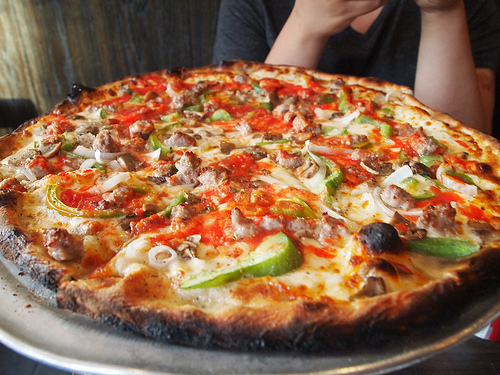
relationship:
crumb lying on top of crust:
[24, 302, 33, 308] [0, 58, 500, 354]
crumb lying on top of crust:
[11, 291, 17, 296] [0, 58, 500, 354]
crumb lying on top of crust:
[16, 270, 26, 277] [0, 58, 500, 354]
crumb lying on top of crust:
[16, 282, 21, 286] [0, 58, 500, 354]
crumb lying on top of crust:
[27, 288, 32, 293] [0, 58, 500, 354]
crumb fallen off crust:
[11, 291, 17, 296] [1, 56, 483, 359]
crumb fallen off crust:
[24, 302, 33, 308] [1, 56, 483, 359]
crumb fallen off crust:
[16, 270, 26, 277] [1, 56, 483, 359]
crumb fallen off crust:
[16, 282, 21, 286] [1, 56, 483, 359]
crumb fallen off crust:
[27, 288, 32, 293] [1, 56, 483, 359]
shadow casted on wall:
[1, 95, 38, 130] [1, 1, 219, 136]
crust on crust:
[1, 220, 499, 353] [0, 58, 500, 354]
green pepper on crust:
[178, 233, 304, 293] [0, 58, 500, 354]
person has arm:
[212, 1, 499, 132] [412, 0, 494, 129]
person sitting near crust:
[212, 1, 499, 132] [0, 58, 500, 354]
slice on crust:
[56, 156, 459, 355] [0, 58, 500, 354]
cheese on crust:
[125, 103, 305, 210] [0, 58, 500, 354]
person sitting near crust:
[210, 0, 498, 136] [0, 58, 500, 354]